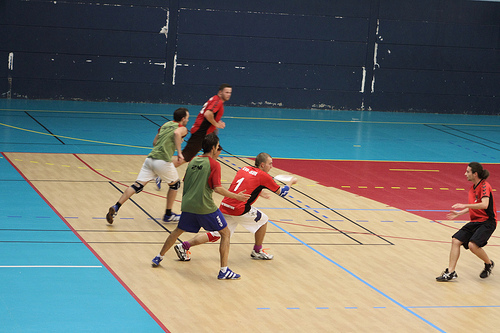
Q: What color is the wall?
A: Blue.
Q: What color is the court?
A: Red and Brown.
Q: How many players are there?
A: 5.